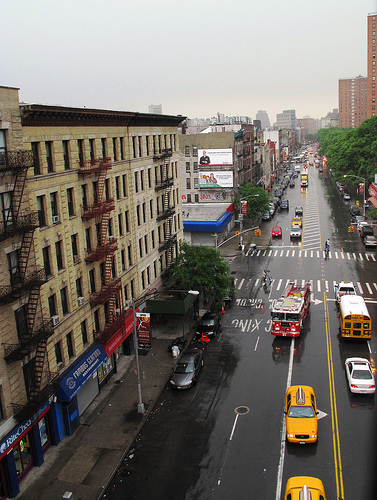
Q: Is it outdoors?
A: Yes, it is outdoors.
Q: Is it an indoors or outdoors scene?
A: It is outdoors.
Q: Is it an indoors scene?
A: No, it is outdoors.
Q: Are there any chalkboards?
A: No, there are no chalkboards.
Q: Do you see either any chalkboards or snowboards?
A: No, there are no chalkboards or snowboards.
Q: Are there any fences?
A: No, there are no fences.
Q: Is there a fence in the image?
A: No, there are no fences.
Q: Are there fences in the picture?
A: No, there are no fences.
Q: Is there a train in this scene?
A: No, there are no trains.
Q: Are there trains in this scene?
A: No, there are no trains.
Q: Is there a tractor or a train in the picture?
A: No, there are no trains or tractors.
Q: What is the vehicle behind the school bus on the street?
A: The vehicle is a car.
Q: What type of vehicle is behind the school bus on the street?
A: The vehicle is a car.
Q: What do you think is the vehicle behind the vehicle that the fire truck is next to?
A: The vehicle is a car.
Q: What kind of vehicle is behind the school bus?
A: The vehicle is a car.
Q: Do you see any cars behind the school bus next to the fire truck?
A: Yes, there is a car behind the school bus.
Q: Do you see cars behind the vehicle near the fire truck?
A: Yes, there is a car behind the school bus.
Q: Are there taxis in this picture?
A: Yes, there is a taxi.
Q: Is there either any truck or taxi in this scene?
A: Yes, there is a taxi.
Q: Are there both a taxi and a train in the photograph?
A: No, there is a taxi but no trains.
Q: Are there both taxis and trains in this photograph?
A: No, there is a taxi but no trains.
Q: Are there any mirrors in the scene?
A: No, there are no mirrors.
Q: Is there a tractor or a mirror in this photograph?
A: No, there are no mirrors or tractors.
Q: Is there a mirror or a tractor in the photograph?
A: No, there are no mirrors or tractors.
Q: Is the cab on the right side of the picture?
A: Yes, the cab is on the right of the image.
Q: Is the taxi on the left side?
A: No, the taxi is on the right of the image.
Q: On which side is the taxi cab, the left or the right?
A: The taxi cab is on the right of the image.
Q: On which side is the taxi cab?
A: The taxi cab is on the right of the image.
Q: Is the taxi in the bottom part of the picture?
A: Yes, the taxi is in the bottom of the image.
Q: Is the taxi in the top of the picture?
A: No, the taxi is in the bottom of the image.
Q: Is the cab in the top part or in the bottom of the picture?
A: The cab is in the bottom of the image.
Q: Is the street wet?
A: Yes, the street is wet.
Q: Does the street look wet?
A: Yes, the street is wet.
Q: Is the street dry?
A: No, the street is wet.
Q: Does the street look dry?
A: No, the street is wet.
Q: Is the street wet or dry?
A: The street is wet.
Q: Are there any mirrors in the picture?
A: No, there are no mirrors.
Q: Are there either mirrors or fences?
A: No, there are no mirrors or fences.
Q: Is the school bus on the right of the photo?
A: Yes, the school bus is on the right of the image.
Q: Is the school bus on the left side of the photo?
A: No, the school bus is on the right of the image.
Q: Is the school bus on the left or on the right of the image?
A: The school bus is on the right of the image.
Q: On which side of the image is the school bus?
A: The school bus is on the right of the image.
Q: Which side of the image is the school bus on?
A: The school bus is on the right of the image.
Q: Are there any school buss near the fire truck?
A: Yes, there is a school bus near the fire truck.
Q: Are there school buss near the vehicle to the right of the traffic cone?
A: Yes, there is a school bus near the fire truck.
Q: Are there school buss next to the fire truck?
A: Yes, there is a school bus next to the fire truck.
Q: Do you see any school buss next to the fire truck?
A: Yes, there is a school bus next to the fire truck.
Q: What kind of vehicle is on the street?
A: The vehicle is a school bus.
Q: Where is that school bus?
A: The school bus is on the street.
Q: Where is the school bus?
A: The school bus is on the street.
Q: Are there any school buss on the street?
A: Yes, there is a school bus on the street.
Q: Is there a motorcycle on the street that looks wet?
A: No, there is a school bus on the street.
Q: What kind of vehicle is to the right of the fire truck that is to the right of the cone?
A: The vehicle is a school bus.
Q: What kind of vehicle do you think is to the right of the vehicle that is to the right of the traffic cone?
A: The vehicle is a school bus.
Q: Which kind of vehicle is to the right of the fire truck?
A: The vehicle is a school bus.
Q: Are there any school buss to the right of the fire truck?
A: Yes, there is a school bus to the right of the fire truck.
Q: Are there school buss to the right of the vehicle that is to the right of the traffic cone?
A: Yes, there is a school bus to the right of the fire truck.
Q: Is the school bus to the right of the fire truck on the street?
A: Yes, the school bus is to the right of the fire truck.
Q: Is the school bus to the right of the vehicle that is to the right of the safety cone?
A: Yes, the school bus is to the right of the fire truck.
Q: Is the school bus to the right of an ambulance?
A: No, the school bus is to the right of the fire truck.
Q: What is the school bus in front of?
A: The school bus is in front of the car.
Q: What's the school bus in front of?
A: The school bus is in front of the car.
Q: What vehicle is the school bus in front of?
A: The school bus is in front of the car.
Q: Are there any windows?
A: Yes, there is a window.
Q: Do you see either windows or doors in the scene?
A: Yes, there is a window.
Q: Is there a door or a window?
A: Yes, there is a window.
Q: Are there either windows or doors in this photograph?
A: Yes, there is a window.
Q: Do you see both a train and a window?
A: No, there is a window but no trains.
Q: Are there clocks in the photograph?
A: No, there are no clocks.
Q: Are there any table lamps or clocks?
A: No, there are no clocks or table lamps.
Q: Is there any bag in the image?
A: No, there are no bags.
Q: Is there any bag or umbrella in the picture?
A: No, there are no bags or umbrellas.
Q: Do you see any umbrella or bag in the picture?
A: No, there are no bags or umbrellas.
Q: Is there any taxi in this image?
A: Yes, there is a taxi.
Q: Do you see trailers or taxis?
A: Yes, there is a taxi.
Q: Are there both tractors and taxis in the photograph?
A: No, there is a taxi but no tractors.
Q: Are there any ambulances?
A: No, there are no ambulances.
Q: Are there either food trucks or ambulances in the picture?
A: No, there are no ambulances or food trucks.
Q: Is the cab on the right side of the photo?
A: Yes, the cab is on the right of the image.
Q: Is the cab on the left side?
A: No, the cab is on the right of the image.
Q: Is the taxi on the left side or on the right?
A: The taxi is on the right of the image.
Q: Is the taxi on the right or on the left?
A: The taxi is on the right of the image.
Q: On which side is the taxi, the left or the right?
A: The taxi is on the right of the image.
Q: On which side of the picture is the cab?
A: The cab is on the right of the image.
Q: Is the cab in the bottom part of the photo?
A: Yes, the cab is in the bottom of the image.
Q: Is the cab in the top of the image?
A: No, the cab is in the bottom of the image.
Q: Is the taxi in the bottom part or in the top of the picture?
A: The taxi is in the bottom of the image.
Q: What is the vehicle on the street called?
A: The vehicle is a taxi.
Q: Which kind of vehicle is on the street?
A: The vehicle is a taxi.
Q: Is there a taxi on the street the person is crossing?
A: Yes, there is a taxi on the street.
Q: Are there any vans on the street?
A: No, there is a taxi on the street.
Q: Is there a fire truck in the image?
A: Yes, there is a fire truck.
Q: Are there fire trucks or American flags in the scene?
A: Yes, there is a fire truck.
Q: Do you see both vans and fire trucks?
A: No, there is a fire truck but no vans.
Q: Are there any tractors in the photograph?
A: No, there are no tractors.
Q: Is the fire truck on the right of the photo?
A: Yes, the fire truck is on the right of the image.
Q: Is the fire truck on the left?
A: No, the fire truck is on the right of the image.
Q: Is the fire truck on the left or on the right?
A: The fire truck is on the right of the image.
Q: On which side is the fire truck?
A: The fire truck is on the right of the image.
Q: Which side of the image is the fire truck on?
A: The fire truck is on the right of the image.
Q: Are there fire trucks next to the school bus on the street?
A: Yes, there is a fire truck next to the school bus.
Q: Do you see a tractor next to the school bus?
A: No, there is a fire truck next to the school bus.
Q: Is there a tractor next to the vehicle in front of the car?
A: No, there is a fire truck next to the school bus.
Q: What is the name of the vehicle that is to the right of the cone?
A: The vehicle is a fire truck.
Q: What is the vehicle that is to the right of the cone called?
A: The vehicle is a fire truck.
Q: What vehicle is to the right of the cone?
A: The vehicle is a fire truck.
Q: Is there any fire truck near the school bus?
A: Yes, there is a fire truck near the school bus.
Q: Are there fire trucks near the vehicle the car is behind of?
A: Yes, there is a fire truck near the school bus.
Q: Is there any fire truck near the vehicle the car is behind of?
A: Yes, there is a fire truck near the school bus.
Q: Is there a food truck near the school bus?
A: No, there is a fire truck near the school bus.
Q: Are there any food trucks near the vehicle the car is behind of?
A: No, there is a fire truck near the school bus.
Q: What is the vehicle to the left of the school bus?
A: The vehicle is a fire truck.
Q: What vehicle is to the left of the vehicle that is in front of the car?
A: The vehicle is a fire truck.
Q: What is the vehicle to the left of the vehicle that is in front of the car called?
A: The vehicle is a fire truck.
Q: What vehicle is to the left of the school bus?
A: The vehicle is a fire truck.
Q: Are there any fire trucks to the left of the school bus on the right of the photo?
A: Yes, there is a fire truck to the left of the school bus.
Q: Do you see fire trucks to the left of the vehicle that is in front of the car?
A: Yes, there is a fire truck to the left of the school bus.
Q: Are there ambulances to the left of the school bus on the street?
A: No, there is a fire truck to the left of the school bus.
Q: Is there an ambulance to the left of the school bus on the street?
A: No, there is a fire truck to the left of the school bus.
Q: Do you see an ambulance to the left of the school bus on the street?
A: No, there is a fire truck to the left of the school bus.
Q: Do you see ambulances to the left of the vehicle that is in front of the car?
A: No, there is a fire truck to the left of the school bus.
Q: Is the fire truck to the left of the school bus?
A: Yes, the fire truck is to the left of the school bus.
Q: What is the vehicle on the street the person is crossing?
A: The vehicle is a fire truck.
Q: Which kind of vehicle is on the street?
A: The vehicle is a fire truck.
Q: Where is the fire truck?
A: The fire truck is on the street.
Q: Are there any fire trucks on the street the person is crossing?
A: Yes, there is a fire truck on the street.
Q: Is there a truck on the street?
A: No, there is a fire truck on the street.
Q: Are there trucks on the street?
A: No, there is a fire truck on the street.